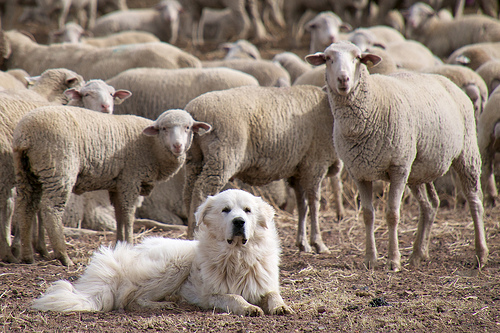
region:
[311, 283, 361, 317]
this is the grass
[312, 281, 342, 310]
the grass is cut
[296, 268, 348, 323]
the grass is brown in color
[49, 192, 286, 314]
this is a dog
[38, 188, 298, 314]
the dog is big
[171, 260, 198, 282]
the fur is white in color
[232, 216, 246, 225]
this is a nose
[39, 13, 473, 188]
these are some sheep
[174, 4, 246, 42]
the wool is white in color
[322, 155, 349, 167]
the wool is rugged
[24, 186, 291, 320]
WHITE DOG LAYING IN HAY ON GROUND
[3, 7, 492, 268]
HERD OF SHEEP BEHIND THE DOG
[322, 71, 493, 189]
SHEEP ARE SHEARED FOR THEIR WOOL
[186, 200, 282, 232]
DOGS EARS ARE HANGING DOWN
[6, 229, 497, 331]
HAY IS COVERING GROUND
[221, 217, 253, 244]
DOGS NOSE IS BLACK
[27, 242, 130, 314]
DOG HAS BUSHY TAIL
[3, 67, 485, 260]
THE SHEEP ARE ALL WHITE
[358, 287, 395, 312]
SMALL CLUMP OF GRASS IN HAY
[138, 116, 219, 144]
THE SHEEPS EARS STICK OUT ON SIDE OF HEAD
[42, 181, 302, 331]
the white dog laying on the ground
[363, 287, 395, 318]
a pile of feces on the ground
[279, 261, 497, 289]
the straw hay on the dirt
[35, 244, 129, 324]
the furry white tail of the dog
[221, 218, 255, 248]
the drooping mouth of the dog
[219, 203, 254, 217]
The black eyes of the dog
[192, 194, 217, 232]
the ear of the dog hanging down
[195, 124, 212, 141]
the white tag in the dogs ear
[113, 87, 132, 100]
the inner pinke ear of the sheep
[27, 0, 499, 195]
the herd of sheep in the kennel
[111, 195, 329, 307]
this is a dog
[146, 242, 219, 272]
the dog is white in color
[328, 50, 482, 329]
this is a sheep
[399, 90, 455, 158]
the sheep is white in color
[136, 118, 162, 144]
this is the ear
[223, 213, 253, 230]
this is the nose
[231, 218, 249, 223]
the nose is black in color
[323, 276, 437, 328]
this is the ground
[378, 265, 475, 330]
the grass is dry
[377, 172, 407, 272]
this is the leg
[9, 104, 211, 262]
sheep is next to sheep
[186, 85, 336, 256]
sheep is next to sheep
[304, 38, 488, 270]
sheep is next to sheep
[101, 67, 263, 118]
sheep is next to sheep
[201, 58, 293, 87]
sheep is next to sheep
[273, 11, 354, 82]
sheep is next to sheep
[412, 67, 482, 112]
sheep is next to sheep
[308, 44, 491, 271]
sheep is in front of sheep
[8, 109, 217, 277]
sheep is in front of sheep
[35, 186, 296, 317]
dog is in front of sheep